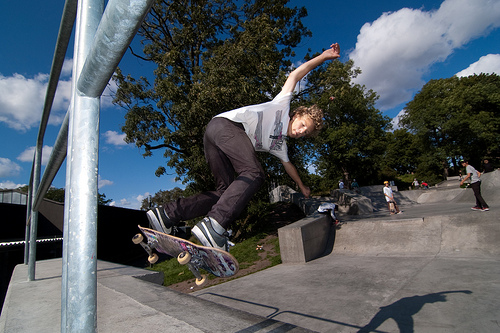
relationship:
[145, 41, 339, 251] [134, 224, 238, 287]
boy on skateboard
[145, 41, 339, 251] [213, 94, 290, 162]
boy wearing shirt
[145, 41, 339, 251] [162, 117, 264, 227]
boy wearing black jeans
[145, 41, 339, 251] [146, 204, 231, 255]
boy wearing tennis shoes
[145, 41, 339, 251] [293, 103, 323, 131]
boy with blonde hair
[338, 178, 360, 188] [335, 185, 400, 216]
spectators near ramp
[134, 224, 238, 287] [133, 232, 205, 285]
skateboard with four wheels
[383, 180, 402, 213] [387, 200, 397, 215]
boy leaning on skateboard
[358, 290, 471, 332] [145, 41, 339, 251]
shadow of boy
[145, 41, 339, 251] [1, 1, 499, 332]
boy in air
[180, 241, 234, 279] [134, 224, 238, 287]
pictures under skateboard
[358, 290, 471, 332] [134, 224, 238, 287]
shadow of skateboard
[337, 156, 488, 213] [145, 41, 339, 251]
peaple watching skateboarder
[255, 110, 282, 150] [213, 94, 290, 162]
gray stripes on shirt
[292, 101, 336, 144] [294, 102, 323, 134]
helmet not worn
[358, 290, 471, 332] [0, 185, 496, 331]
shadow on ground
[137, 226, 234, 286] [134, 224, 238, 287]
underside of skateboard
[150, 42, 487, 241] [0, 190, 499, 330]
kids at a skatepark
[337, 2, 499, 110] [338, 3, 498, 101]
clouds in formation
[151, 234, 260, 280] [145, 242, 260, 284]
patch of grass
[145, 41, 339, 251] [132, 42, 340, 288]
boy doing skateboard trick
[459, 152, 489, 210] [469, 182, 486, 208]
person wearing dark pants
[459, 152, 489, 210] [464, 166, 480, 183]
person wearing white shirt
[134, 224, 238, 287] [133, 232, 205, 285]
skateboard with wheels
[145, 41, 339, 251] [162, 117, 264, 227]
boy wearing black pants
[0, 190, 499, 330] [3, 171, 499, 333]
skate park made with cement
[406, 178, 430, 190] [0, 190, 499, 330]
people sitting in skatepark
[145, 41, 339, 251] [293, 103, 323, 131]
person has blonde hair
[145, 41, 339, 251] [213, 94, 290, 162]
person wearing white shirt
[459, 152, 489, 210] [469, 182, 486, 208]
person wearing black pants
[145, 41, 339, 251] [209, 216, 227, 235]
person wearing white socks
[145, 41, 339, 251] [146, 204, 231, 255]
person wearing shoes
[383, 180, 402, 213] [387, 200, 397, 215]
person standing on skateboard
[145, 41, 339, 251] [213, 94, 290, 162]
person wearing t-shirt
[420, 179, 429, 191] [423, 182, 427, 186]
person wearing red shirt